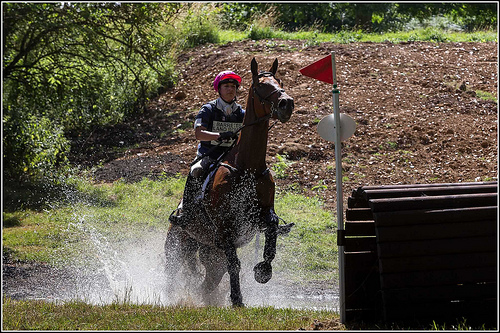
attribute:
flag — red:
[299, 54, 332, 86]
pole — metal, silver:
[331, 50, 345, 326]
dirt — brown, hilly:
[78, 34, 497, 218]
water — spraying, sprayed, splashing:
[24, 117, 274, 307]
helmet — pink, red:
[212, 69, 242, 93]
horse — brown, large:
[162, 56, 297, 307]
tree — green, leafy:
[0, 1, 185, 124]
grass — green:
[2, 297, 339, 329]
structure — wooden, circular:
[341, 179, 498, 329]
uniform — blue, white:
[191, 97, 245, 162]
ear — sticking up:
[247, 56, 261, 80]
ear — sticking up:
[269, 54, 280, 74]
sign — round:
[316, 113, 358, 148]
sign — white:
[208, 120, 243, 147]